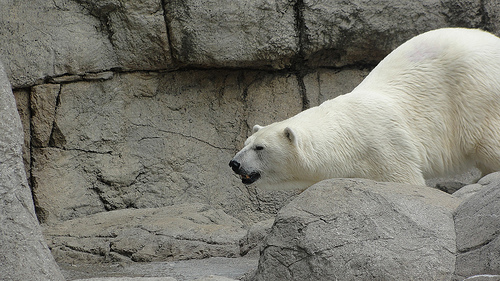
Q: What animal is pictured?
A: A polar bear.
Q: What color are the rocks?
A: Gray.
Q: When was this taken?
A: Daytime.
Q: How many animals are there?
A: 1.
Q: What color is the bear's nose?
A: Black.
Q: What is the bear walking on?
A: Rocks.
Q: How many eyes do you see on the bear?
A: 1.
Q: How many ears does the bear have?
A: 2.